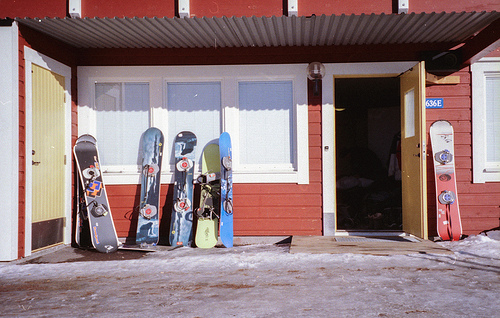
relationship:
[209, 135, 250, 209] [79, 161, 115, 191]
snowboard has graphics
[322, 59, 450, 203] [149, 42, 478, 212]
door of business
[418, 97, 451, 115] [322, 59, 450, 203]
636e by door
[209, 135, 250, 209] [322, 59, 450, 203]
snowboard by door